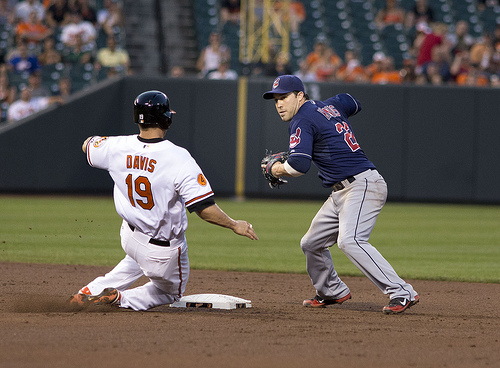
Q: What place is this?
A: It is a field.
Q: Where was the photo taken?
A: It was taken at the field.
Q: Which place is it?
A: It is a field.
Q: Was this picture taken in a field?
A: Yes, it was taken in a field.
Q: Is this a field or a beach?
A: It is a field.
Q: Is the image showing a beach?
A: No, the picture is showing a field.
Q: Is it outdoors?
A: Yes, it is outdoors.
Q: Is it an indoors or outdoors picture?
A: It is outdoors.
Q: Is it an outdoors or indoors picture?
A: It is outdoors.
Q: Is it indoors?
A: No, it is outdoors.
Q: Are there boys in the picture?
A: No, there are no boys.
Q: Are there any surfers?
A: No, there are no surfers.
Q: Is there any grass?
A: Yes, there is grass.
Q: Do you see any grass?
A: Yes, there is grass.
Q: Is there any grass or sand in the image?
A: Yes, there is grass.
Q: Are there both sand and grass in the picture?
A: No, there is grass but no sand.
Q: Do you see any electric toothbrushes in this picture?
A: No, there are no electric toothbrushes.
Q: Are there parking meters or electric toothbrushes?
A: No, there are no electric toothbrushes or parking meters.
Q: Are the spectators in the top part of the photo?
A: Yes, the spectators are in the top of the image.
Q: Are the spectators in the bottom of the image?
A: No, the spectators are in the top of the image.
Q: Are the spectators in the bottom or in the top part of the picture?
A: The spectators are in the top of the image.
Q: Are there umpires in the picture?
A: No, there are no umpires.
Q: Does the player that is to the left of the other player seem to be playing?
A: Yes, the player is playing.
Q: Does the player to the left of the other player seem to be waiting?
A: No, the player is playing.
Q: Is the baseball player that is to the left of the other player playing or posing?
A: The player is playing.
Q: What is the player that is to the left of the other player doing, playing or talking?
A: The player is playing.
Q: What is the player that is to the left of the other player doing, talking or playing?
A: The player is playing.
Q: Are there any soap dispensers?
A: No, there are no soap dispensers.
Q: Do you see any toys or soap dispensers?
A: No, there are no soap dispensers or toys.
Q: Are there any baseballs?
A: Yes, there is a baseball.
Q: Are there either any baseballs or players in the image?
A: Yes, there is a baseball.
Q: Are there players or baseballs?
A: Yes, there is a baseball.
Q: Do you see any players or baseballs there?
A: Yes, there is a baseball.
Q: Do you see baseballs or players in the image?
A: Yes, there is a baseball.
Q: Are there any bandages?
A: No, there are no bandages.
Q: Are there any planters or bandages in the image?
A: No, there are no bandages or planters.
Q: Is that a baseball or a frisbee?
A: That is a baseball.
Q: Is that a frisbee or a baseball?
A: That is a baseball.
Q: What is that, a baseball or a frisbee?
A: That is a baseball.